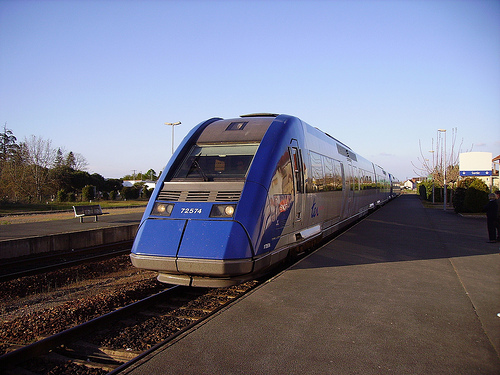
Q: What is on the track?
A: Blue and grey train.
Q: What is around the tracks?
A: Gravel.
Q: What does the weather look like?
A: Sunny.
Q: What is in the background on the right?
A: A big blue and white sign.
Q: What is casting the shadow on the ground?
A: The train.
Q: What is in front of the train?
A: The train tracks.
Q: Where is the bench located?
A: Platform.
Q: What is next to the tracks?
A: Cement.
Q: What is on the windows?
A: Glass.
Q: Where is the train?
A: On the tracks.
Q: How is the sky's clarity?
A: Clear.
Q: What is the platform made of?
A: Concrete.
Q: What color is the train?
A: Blue.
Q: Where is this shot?
A: Train stop.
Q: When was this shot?
A: Daytime.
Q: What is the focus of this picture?
A: Train at station.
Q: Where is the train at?
A: Station.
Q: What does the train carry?
A: People.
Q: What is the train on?
A: Tracks.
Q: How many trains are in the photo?
A: 1.